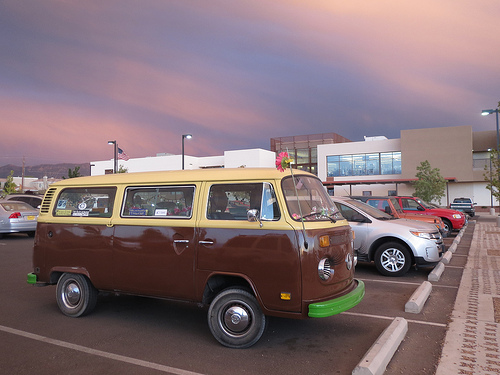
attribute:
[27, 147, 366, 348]
van — brown, old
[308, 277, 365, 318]
bumper — green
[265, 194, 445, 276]
car — silver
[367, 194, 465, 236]
car — red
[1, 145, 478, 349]
cars — parked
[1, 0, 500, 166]
sky — overcast, multi colored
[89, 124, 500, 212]
building — white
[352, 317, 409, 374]
block — cement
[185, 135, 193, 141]
light — lit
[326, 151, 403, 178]
window — glass, large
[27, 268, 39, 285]
bumper — green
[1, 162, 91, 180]
mountain — far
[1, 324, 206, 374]
line — white